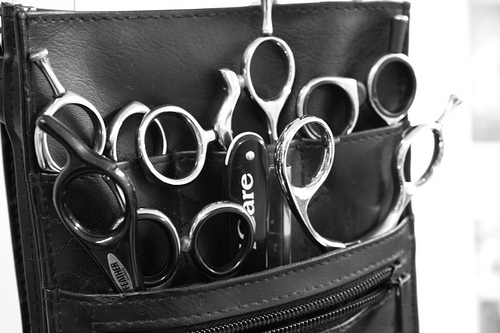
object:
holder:
[0, 1, 420, 333]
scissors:
[273, 94, 463, 253]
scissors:
[297, 14, 419, 137]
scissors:
[135, 1, 293, 268]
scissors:
[36, 114, 141, 295]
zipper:
[180, 266, 394, 333]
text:
[238, 173, 257, 252]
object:
[226, 130, 268, 274]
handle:
[91, 236, 144, 294]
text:
[109, 261, 130, 292]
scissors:
[102, 175, 256, 294]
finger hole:
[143, 109, 199, 180]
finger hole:
[113, 112, 165, 161]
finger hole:
[138, 214, 177, 283]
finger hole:
[63, 170, 128, 236]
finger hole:
[193, 206, 251, 275]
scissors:
[29, 48, 168, 173]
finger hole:
[48, 104, 105, 169]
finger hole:
[228, 86, 273, 145]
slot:
[55, 211, 409, 295]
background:
[0, 1, 499, 333]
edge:
[55, 218, 409, 301]